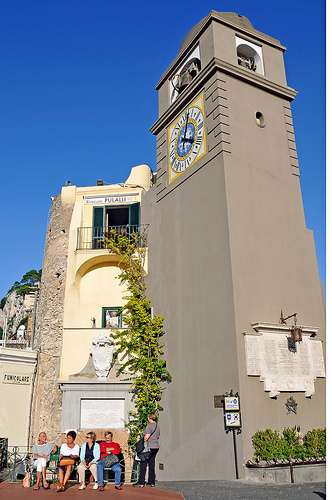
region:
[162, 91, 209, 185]
the face of a clock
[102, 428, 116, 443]
the head of a man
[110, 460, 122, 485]
the leg of a man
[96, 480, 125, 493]
a pair of shoes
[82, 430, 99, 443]
the head of a woman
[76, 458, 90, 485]
the leg of a woman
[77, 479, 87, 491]
a white shoe on the woman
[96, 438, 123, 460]
a red shirt on the man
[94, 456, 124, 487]
a pair of blue jeans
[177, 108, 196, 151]
black hands on the clock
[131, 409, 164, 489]
woman carries large bag, possibly w/ toddler [?]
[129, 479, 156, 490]
woman in black pants wears clogs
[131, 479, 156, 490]
sun reflects from the soles of the clogs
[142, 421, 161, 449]
woman wears grey top, crossbody bag across it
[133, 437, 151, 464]
crossbody bag is in blacks, maybe dark blues, & grey tones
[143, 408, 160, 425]
woman has short, not particularly thick, blonde hair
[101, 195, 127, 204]
'pulalli' -this is the pulalli wine bar in capri, italy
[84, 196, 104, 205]
the blurry word before 'pulalli' [in all caps] is 'ristorante' [only cap is first letter]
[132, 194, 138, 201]
this is a picture of what i think's supposed to be wine but looks like beer. it's printed, not a photo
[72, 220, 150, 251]
small balcony before pulalli wine bar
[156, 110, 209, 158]
clock on side of building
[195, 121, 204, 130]
roman numeral on clock face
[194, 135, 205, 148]
roman numeral on clock face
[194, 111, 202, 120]
roman numeral on clock face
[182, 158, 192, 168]
roman numeral on clock face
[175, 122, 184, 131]
roman numeral on clock face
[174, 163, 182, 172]
roman numeral on clock face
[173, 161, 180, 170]
roman numeral on clock face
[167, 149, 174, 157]
roman numeral on clock face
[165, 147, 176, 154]
roman numeral on clock face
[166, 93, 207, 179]
a white, yellow, and blue clock face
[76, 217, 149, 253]
a balcony railing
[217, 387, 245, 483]
a sign next to a building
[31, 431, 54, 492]
a person in a gray shirt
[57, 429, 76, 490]
a woman in a white shirt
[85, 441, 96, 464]
a navy shirt on a woman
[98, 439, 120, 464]
a red shirt on a man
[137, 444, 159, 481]
black pants on a woman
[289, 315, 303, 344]
a lamp hanging off a wall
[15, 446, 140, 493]
a metal bench holding people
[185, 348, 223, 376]
the tower is gray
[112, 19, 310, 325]
the tower is short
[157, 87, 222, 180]
the clock is on the tower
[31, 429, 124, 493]
the people are sitting on the bench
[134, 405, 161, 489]
the woman is standing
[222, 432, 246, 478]
the pole is black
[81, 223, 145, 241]
the railing is metal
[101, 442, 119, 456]
the shirt is red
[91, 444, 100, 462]
the sweater is light blue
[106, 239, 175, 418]
the vine is long